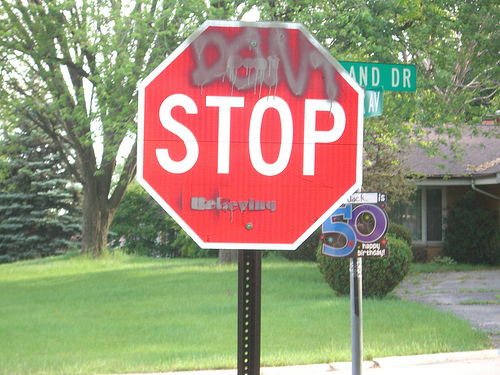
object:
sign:
[134, 20, 369, 252]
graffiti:
[182, 25, 343, 100]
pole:
[236, 246, 264, 374]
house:
[380, 120, 500, 264]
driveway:
[392, 268, 499, 352]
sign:
[322, 195, 389, 263]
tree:
[0, 96, 86, 267]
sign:
[337, 56, 419, 119]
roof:
[395, 119, 499, 175]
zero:
[353, 203, 390, 247]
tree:
[320, 230, 418, 301]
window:
[407, 185, 446, 245]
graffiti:
[193, 194, 280, 219]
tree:
[0, 2, 208, 263]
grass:
[1, 249, 495, 374]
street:
[131, 339, 432, 372]